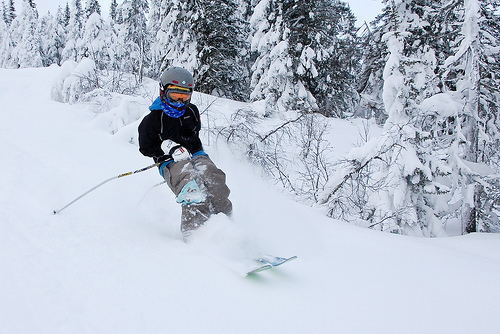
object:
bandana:
[148, 92, 186, 119]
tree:
[168, 0, 248, 100]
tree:
[245, 2, 350, 116]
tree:
[53, 2, 81, 66]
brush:
[225, 103, 344, 213]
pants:
[153, 154, 232, 232]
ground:
[400, 152, 422, 180]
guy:
[137, 67, 232, 245]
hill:
[0, 63, 498, 326]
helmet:
[157, 65, 195, 107]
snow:
[41, 28, 118, 128]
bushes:
[234, 67, 478, 232]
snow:
[338, 229, 450, 280]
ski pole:
[54, 158, 171, 214]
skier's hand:
[170, 144, 194, 163]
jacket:
[138, 103, 203, 168]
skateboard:
[190, 231, 297, 274]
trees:
[347, 0, 451, 231]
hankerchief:
[147, 94, 193, 120]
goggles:
[155, 80, 194, 104]